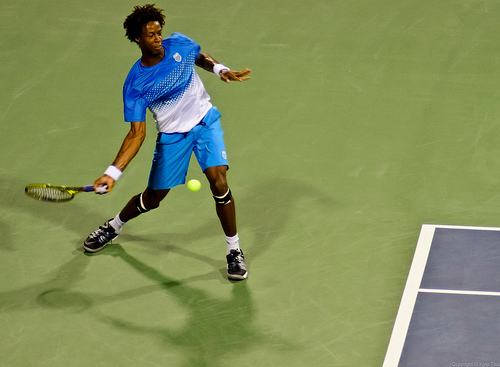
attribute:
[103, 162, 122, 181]
sweat band — white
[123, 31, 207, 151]
jersey — blue, white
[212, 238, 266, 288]
tennis shoe — black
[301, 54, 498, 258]
pavement — leveled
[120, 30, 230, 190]
uniform — blue, white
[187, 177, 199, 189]
tennis ball — bright yellow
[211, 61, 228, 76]
wrist band — white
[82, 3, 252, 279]
man — player, african, american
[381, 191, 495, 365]
square — blue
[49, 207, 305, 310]
shoes — player's, black, white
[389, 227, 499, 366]
square — blue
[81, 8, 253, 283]
player — wearing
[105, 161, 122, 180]
wrist band — white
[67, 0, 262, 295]
player — tennis, swinging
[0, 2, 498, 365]
court — tennis, blue, concrete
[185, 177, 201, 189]
ball — tennis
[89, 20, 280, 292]
player — tennis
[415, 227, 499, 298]
square — blue